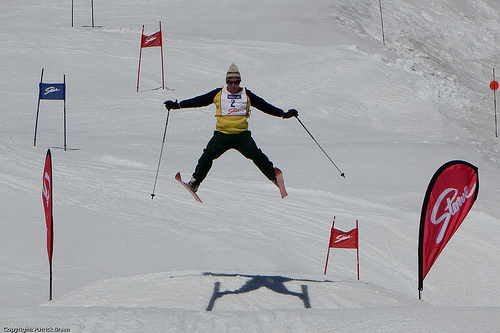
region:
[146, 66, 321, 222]
man in the air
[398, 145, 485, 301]
red flag in snow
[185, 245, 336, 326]
shadow of man on snow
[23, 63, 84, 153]
blue flag in snow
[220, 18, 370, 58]
fresh powdered snow bank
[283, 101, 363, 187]
ski poles in hands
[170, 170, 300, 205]
Red skies on feet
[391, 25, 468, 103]
bumpy white snow bank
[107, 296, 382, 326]
bump in snow bank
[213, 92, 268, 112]
number 2 on shirt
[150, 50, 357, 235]
man is in the air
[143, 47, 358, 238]
Person is in mid air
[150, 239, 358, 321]
Person is casting a shadow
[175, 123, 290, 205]
Person is wearing black pants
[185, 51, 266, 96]
Person is wearing sunglasses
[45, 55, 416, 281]
Ground is covered in snow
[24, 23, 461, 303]
Photo was taken in the daytime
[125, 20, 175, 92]
A red flag with two pole is in the background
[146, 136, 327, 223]
Person's legs are spread open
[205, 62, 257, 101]
Man is wearing a tan colored cap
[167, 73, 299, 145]
Person is wearing a yellow and black shirt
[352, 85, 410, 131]
part of a snow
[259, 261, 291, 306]
part of a shade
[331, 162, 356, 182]
part of a hooker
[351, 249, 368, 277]
part of a stand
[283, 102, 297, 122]
part of a glove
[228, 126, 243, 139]
part of a jumper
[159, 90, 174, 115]
part of a right glove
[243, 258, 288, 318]
shade of the skater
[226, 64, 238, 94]
face of the skater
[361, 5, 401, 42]
part of a stand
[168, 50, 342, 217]
male skier performing jump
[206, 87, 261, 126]
male skier wearing white racing bib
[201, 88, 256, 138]
male skier wearing yellow top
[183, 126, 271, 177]
male skier wearing black panats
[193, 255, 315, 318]
black shadow of male skier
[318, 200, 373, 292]
red and white flag in snow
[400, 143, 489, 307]
red and white flag in snow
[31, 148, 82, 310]
red and white flag in snow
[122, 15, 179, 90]
red and white flag in snow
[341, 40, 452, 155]
white snow on mountain